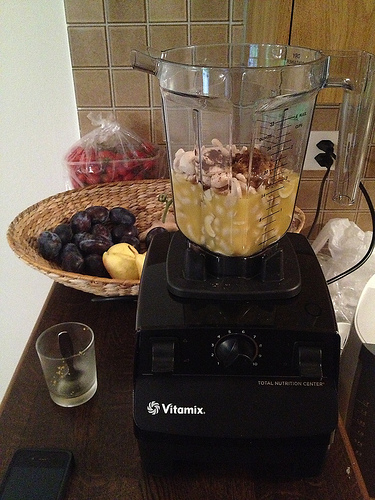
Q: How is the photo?
A: Clear.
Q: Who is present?
A: Nobody.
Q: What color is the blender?
A: Black.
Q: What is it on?
A: Kitchen table.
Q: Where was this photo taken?
A: In a kitchen.